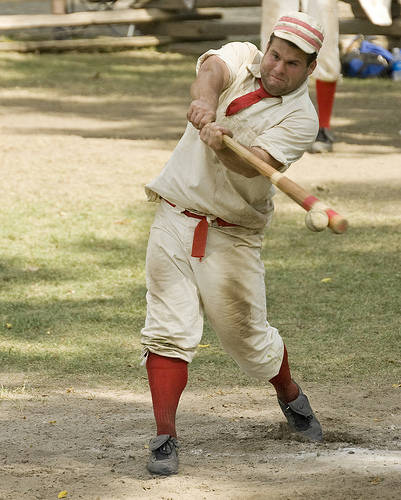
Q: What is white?
A: Batter's uniform.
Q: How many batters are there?
A: One.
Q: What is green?
A: Grass.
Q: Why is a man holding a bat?
A: To hit a ball.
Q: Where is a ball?
A: In the air.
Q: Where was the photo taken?
A: At a baseball game.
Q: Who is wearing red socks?
A: The batter.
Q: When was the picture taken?
A: Daytime.